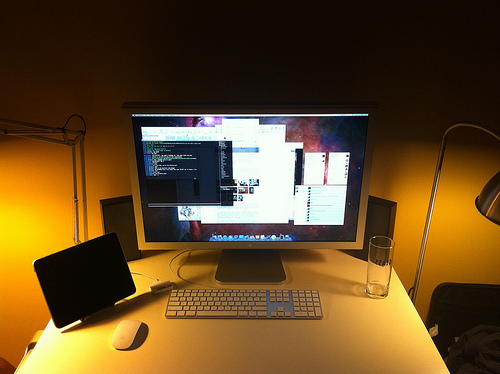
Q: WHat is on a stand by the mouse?
A: An ipad mini.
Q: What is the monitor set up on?
A: A large white table.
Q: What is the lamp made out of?
A: Stainless steel.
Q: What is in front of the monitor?
A: Keyboard.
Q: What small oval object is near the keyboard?
A: Mouse.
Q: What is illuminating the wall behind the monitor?
A: Floor lamp.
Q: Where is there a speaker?
A: Behind the monitor.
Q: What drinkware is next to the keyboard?
A: Glass tumbler.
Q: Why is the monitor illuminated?
A: Because it is on.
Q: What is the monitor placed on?
A: Stand.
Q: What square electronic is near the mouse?
A: Tablet.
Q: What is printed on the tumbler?
A: GLASS.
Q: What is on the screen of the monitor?
A: Programs opened.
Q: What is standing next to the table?
A: A silver floor lamp.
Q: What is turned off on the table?
A: A clock.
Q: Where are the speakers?
A: Behind the monitor.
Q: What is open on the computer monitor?
A: Tasks.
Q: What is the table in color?
A: White.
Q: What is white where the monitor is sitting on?
A: The table.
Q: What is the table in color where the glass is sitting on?
A: White.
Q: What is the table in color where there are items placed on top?
A: White.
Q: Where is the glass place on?
A: The white table.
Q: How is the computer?
A: On.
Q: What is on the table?
A: Computer.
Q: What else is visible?
A: Keyboard.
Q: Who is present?
A: No one.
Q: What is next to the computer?
A: Glass.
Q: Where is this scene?
A: In an office.